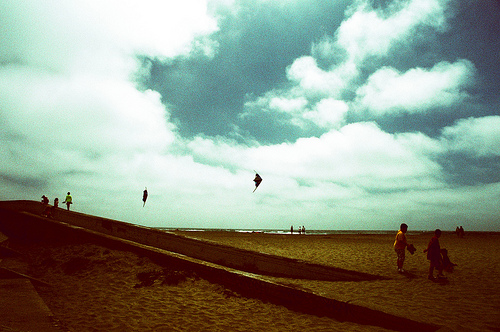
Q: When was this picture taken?
A: Day time.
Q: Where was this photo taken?
A: The beach.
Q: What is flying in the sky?
A: Kites.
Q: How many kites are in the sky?
A: Two.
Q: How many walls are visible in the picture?
A: Two.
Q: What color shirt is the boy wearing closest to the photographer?
A: Red.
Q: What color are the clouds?
A: White.